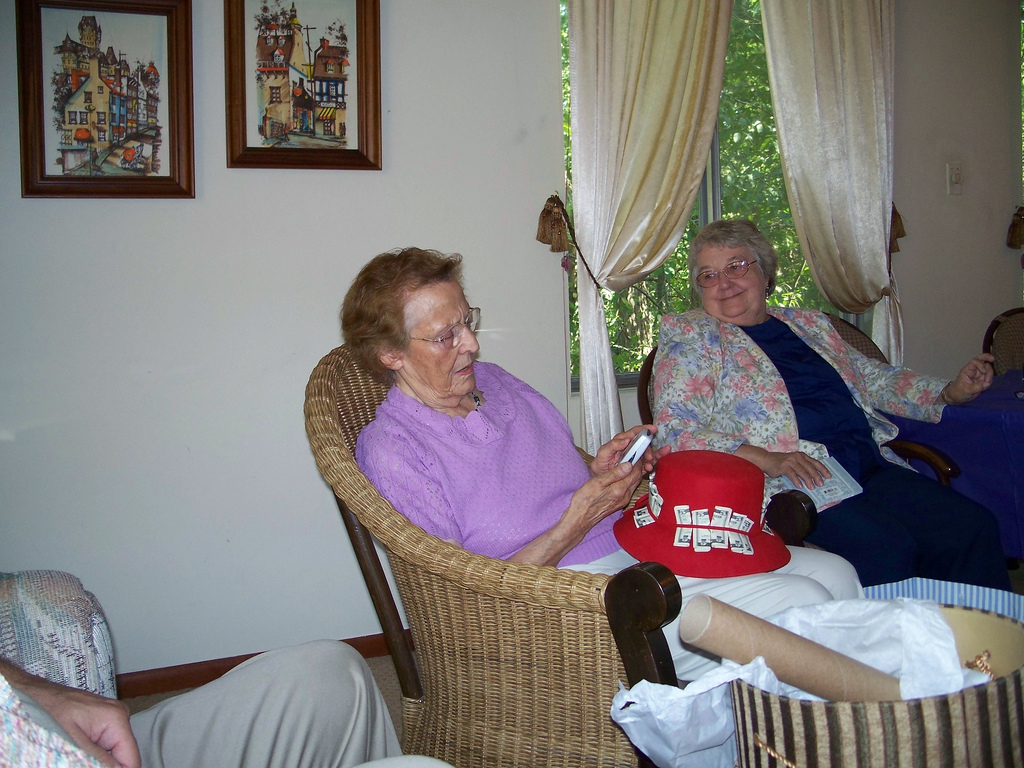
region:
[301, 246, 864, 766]
woman sitting in light brown wicker chair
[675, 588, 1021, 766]
empty roll inside of a giftbag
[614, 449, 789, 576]
money lining a red hat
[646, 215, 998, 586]
older woman in flower jacket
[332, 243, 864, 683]
woman wearing purple shirt and white pants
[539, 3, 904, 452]
cream colored velvet curtains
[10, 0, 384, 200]
two pieces of artwork on the wall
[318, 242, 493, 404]
the head of a woman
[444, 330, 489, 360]
the nose of a woman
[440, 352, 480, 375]
the mouth of a woman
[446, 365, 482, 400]
the chin of a woman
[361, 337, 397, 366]
the ear of a woman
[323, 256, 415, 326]
the hair of a woman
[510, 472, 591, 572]
the arm of a woman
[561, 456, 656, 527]
the hand of a woman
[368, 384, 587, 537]
the shirt of a woman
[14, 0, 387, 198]
the pictures are framed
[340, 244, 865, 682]
the elderly woman is sitting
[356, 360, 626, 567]
the sweater is light purple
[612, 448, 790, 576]
the hat is red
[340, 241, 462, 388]
the hair is short and light brown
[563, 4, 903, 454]
the curtains are hanging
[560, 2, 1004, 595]
the woman sitting in front of the window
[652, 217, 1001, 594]
the woman wearing the floral jacket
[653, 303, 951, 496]
the jacket is floral print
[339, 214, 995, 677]
the two women sitting next to each other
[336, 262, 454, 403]
head of the woman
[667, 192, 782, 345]
head of the woman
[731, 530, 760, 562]
money on the hat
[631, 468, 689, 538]
money on the hat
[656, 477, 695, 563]
money on the hat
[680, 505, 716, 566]
money on the hat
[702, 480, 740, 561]
money on the hat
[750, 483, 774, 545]
money on the hat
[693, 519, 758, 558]
money on the hat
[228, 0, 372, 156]
painting on the wall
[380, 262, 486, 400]
head of the woman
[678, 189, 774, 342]
head of the woman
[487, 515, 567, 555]
arm of the woman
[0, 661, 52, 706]
arm of the woman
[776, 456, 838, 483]
hand of the woman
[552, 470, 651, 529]
hand of the woman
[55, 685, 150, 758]
hand of the woman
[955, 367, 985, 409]
hand of the woman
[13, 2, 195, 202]
brown framed picture hanging on a wall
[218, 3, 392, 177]
brown framed picture hanging on a wall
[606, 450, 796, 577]
large red hat with money in tie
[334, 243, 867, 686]
older woman wearing purple shirt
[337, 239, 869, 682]
older woman wearing white pants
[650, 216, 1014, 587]
older woman wearing floral shirt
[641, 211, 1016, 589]
older woman wearing blue outfit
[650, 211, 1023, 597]
older woman with gray hair wearing glasses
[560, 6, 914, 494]
cream colored curtains pulled back from clear window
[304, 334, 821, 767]
tan wicker chair with dark brown arms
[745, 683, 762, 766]
dark stripe on bag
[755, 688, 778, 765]
dark stripe on bag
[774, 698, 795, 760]
dark stripe on bag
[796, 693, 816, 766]
dark stripe on bag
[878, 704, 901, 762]
dark stripe on bag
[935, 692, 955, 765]
dark stripe on bag